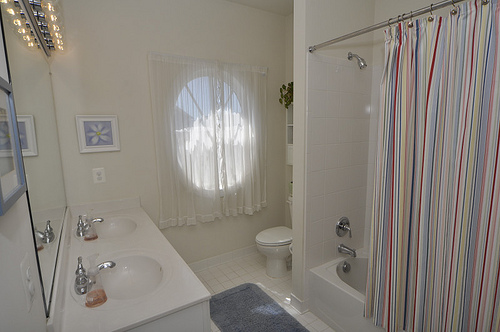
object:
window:
[176, 80, 257, 195]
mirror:
[0, 5, 68, 322]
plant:
[275, 81, 294, 110]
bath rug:
[201, 281, 307, 331]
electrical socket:
[94, 171, 102, 182]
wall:
[55, 4, 292, 250]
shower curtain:
[363, 0, 500, 331]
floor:
[188, 247, 338, 332]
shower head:
[344, 49, 369, 71]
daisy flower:
[84, 120, 112, 148]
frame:
[75, 115, 119, 153]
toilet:
[255, 195, 294, 276]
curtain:
[148, 54, 271, 229]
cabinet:
[281, 92, 296, 165]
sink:
[90, 250, 163, 299]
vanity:
[67, 205, 211, 330]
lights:
[46, 45, 67, 53]